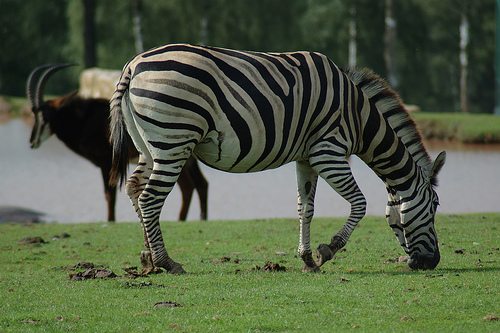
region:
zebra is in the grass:
[99, 21, 454, 293]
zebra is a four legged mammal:
[94, 22, 461, 302]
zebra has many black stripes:
[97, 19, 459, 296]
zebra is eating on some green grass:
[98, 30, 461, 305]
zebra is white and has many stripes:
[94, 31, 462, 300]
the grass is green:
[1, 214, 497, 326]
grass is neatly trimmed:
[1, 208, 498, 326]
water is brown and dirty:
[4, 101, 499, 235]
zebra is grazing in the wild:
[96, 22, 457, 284]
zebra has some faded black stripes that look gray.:
[97, 21, 454, 291]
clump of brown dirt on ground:
[58, 255, 119, 295]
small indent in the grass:
[143, 297, 197, 318]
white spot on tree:
[450, 22, 481, 71]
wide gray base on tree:
[369, 25, 414, 65]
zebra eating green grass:
[406, 243, 452, 271]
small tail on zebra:
[86, 70, 142, 132]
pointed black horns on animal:
[18, 62, 65, 115]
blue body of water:
[15, 148, 82, 201]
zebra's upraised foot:
[313, 228, 369, 279]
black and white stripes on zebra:
[179, 67, 311, 117]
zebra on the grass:
[93, 40, 446, 279]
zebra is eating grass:
[398, 248, 443, 276]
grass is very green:
[2, 209, 497, 331]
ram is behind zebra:
[18, 53, 217, 228]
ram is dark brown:
[16, 57, 212, 224]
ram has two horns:
[15, 51, 79, 154]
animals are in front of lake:
[3, 108, 497, 224]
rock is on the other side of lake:
[72, 61, 134, 103]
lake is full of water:
[2, 111, 499, 224]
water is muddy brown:
[1, 108, 499, 226]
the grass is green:
[189, 233, 310, 327]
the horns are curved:
[21, 63, 74, 108]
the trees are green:
[299, 13, 447, 26]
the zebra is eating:
[112, 61, 447, 271]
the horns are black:
[24, 63, 77, 105]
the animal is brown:
[49, 101, 121, 196]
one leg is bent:
[302, 165, 384, 275]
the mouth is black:
[406, 256, 464, 297]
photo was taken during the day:
[6, 4, 498, 312]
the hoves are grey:
[294, 242, 351, 268]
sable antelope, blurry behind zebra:
[17, 56, 217, 218]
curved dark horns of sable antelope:
[20, 57, 82, 105]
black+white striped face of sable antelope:
[24, 107, 59, 152]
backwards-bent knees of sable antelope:
[174, 153, 215, 220]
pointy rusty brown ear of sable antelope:
[48, 86, 82, 109]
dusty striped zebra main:
[333, 61, 440, 186]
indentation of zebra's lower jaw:
[383, 191, 423, 260]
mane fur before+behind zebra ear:
[425, 148, 448, 188]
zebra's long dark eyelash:
[432, 193, 445, 211]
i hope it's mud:
[1, 216, 496, 332]